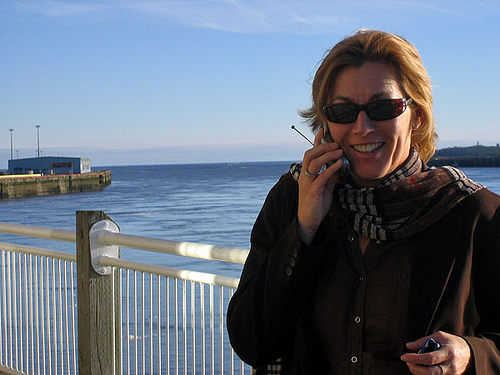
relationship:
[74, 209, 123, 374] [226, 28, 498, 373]
post by woman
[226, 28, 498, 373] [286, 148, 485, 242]
woman has scarf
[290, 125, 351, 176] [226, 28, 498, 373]
cell phone in woman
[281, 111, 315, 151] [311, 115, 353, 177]
antenna on cell phone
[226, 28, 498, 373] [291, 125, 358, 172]
woman holding cell phone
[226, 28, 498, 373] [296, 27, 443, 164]
woman has hair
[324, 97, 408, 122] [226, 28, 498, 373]
sunglasses on woman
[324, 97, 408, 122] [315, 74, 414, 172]
sunglasses on face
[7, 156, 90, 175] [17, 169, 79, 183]
building on pier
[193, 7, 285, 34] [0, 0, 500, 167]
cloud in sky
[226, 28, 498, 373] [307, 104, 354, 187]
woman on cellphone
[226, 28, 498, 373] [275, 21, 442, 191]
woman wearing sunglasses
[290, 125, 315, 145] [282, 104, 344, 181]
antenna on cellphone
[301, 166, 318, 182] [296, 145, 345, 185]
ring on finger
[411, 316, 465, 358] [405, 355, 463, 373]
ring on finger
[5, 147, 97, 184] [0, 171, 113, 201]
building at end of pier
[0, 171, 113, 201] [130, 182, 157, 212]
pier in ocean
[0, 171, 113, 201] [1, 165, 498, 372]
pier jutting into ocean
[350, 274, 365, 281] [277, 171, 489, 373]
button on front of sweater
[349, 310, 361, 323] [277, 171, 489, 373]
button on front of sweater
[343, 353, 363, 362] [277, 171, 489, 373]
button on front of sweater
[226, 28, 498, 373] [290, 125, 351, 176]
woman talking on cell phone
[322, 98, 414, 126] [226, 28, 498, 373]
sunglasses on woman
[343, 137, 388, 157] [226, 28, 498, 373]
smile on woman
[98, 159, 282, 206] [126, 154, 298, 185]
waves in water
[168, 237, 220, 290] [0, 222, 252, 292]
sunlight reflecting off railing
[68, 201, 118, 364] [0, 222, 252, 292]
post holds railing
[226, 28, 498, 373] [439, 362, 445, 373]
woman has ring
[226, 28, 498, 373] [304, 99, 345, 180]
woman has phone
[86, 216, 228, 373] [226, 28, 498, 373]
railing behind woman